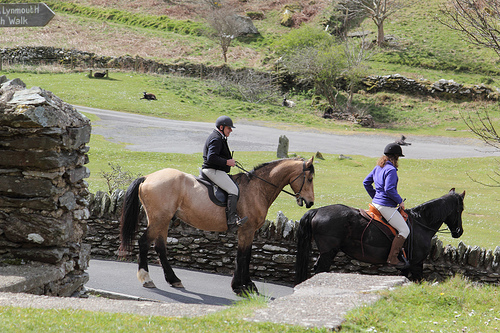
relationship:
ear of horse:
[447, 185, 458, 195] [289, 182, 474, 287]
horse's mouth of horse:
[296, 197, 310, 209] [117, 159, 317, 299]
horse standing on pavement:
[117, 159, 317, 299] [81, 249, 296, 307]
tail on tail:
[114, 168, 149, 264] [117, 172, 144, 259]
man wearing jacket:
[195, 104, 250, 234] [202, 125, 234, 173]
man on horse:
[195, 104, 250, 234] [108, 147, 324, 307]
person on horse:
[361, 135, 412, 270] [289, 182, 474, 287]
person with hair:
[361, 135, 412, 270] [376, 156, 396, 167]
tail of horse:
[104, 162, 174, 263] [74, 127, 344, 305]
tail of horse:
[294, 203, 320, 283] [302, 199, 464, 278]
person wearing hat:
[361, 135, 412, 270] [361, 119, 420, 157]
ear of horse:
[303, 152, 315, 167] [117, 159, 317, 299]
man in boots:
[174, 100, 284, 234] [186, 175, 258, 235]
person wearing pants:
[361, 135, 412, 270] [371, 197, 410, 239]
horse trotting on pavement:
[117, 149, 316, 298] [84, 258, 293, 301]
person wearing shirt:
[361, 135, 412, 270] [368, 154, 400, 205]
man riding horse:
[195, 104, 250, 234] [141, 143, 319, 263]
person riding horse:
[370, 135, 412, 222] [299, 170, 475, 285]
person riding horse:
[361, 135, 412, 270] [292, 194, 465, 281]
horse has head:
[117, 149, 316, 298] [290, 155, 316, 208]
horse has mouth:
[117, 149, 316, 298] [295, 194, 315, 208]